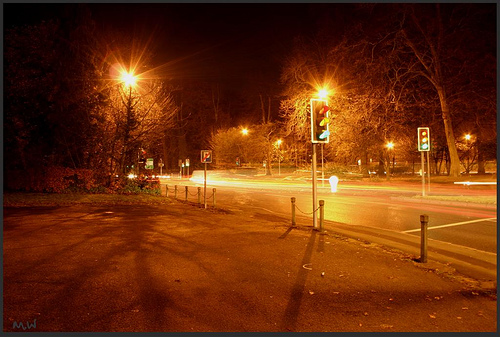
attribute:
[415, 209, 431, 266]
barrier — gray, metal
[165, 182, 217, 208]
fence — pole, chain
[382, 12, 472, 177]
tree — large 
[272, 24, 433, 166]
tree — large 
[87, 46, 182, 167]
tree — large 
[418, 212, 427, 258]
barrier — grey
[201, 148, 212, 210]
sign — blue and white , no parking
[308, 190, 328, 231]
barrier — grey 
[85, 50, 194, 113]
light — street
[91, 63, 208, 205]
light — bright 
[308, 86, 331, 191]
street light — bright 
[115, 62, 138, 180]
street light — bright 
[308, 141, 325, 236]
pole — metal 